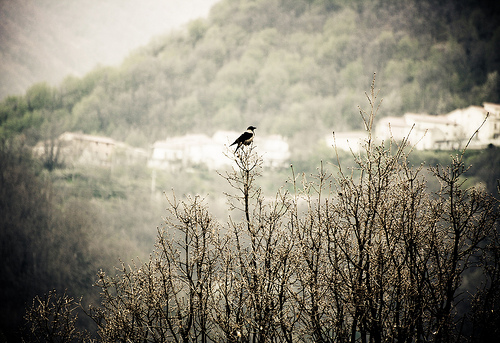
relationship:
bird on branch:
[228, 121, 259, 151] [222, 155, 261, 254]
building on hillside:
[30, 126, 150, 183] [11, 60, 491, 177]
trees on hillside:
[0, 0, 498, 143] [3, 1, 499, 341]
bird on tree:
[228, 125, 258, 154] [0, 142, 500, 339]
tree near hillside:
[0, 142, 500, 339] [0, 1, 498, 271]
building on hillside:
[324, 102, 497, 156] [92, 22, 497, 254]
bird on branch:
[228, 125, 258, 154] [224, 141, 261, 241]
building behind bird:
[324, 97, 497, 177] [228, 125, 258, 154]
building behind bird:
[150, 125, 285, 163] [228, 125, 258, 154]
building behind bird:
[30, 126, 150, 183] [228, 125, 258, 154]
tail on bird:
[232, 140, 240, 153] [229, 125, 257, 154]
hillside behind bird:
[3, 1, 499, 341] [227, 124, 257, 155]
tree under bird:
[322, 142, 491, 339] [230, 124, 258, 157]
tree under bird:
[0, 142, 500, 339] [230, 124, 258, 157]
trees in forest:
[0, 0, 498, 143] [143, 52, 263, 129]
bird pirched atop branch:
[228, 125, 258, 154] [221, 143, 269, 240]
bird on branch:
[228, 125, 258, 154] [217, 137, 262, 232]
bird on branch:
[228, 125, 258, 154] [231, 142, 263, 234]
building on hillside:
[30, 126, 150, 183] [3, 1, 499, 341]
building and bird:
[150, 125, 285, 163] [222, 118, 257, 155]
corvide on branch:
[230, 122, 255, 152] [224, 143, 264, 340]